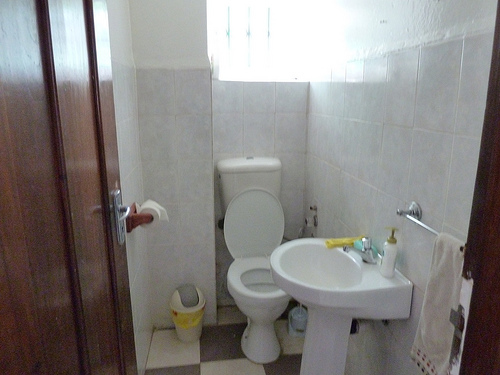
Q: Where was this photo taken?
A: In a bathroom.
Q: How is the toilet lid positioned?
A: Open.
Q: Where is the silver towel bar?
A: Near the sink.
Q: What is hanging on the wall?
A: Towel.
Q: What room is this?
A: Bathroom.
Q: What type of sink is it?
A: Pedestal style.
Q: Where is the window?
A: On the back wall.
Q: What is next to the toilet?
A: A wastebasket.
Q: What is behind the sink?
A: A towel rack.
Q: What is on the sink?
A: A bottle of soap.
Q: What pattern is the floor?
A: Large black and white tiles.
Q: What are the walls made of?
A: White tiles.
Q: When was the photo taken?
A: Daytime.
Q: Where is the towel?
A: Towel rack.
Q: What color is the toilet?
A: White.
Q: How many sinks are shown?
A: One.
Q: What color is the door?
A: Brown.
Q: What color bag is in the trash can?
A: Yellow.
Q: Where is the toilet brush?
A: Right side.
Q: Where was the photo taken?
A: In a house.